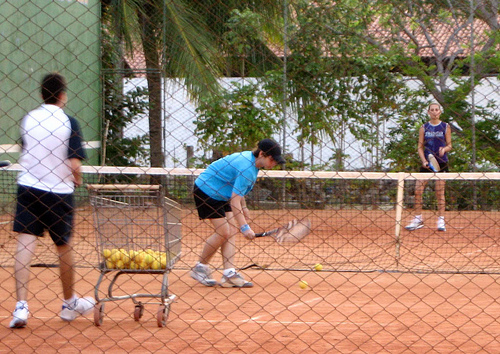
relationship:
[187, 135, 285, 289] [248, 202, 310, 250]
boy holds racket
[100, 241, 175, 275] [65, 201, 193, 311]
balls in cart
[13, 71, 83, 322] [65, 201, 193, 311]
man near cart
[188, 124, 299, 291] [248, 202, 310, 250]
boy has racket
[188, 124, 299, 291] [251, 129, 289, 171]
boy has cap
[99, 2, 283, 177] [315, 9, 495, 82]
tree behind fence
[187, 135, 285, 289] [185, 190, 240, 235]
boy wears shorts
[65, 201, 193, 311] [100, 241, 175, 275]
cart holds balls